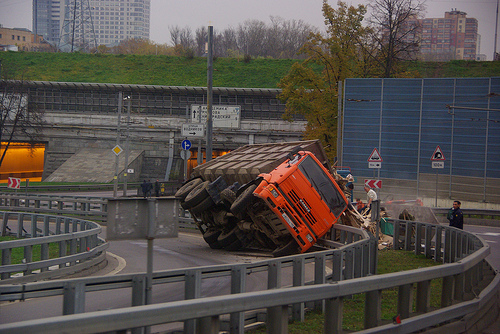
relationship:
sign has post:
[431, 146, 448, 163] [434, 171, 440, 222]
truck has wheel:
[173, 137, 349, 255] [233, 186, 256, 214]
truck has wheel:
[173, 137, 349, 255] [274, 238, 292, 256]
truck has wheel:
[173, 137, 349, 255] [188, 184, 213, 211]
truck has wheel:
[173, 137, 349, 255] [171, 179, 203, 197]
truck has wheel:
[173, 137, 349, 255] [217, 231, 243, 252]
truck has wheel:
[173, 137, 349, 255] [200, 226, 225, 251]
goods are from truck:
[310, 185, 477, 269] [127, 135, 357, 266]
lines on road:
[93, 249, 136, 279] [25, 205, 338, 330]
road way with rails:
[99, 208, 301, 280] [158, 250, 400, 324]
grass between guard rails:
[317, 237, 453, 327] [196, 219, 381, 284]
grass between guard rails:
[317, 237, 453, 327] [398, 219, 497, 324]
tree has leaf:
[278, 2, 388, 162] [323, 7, 328, 13]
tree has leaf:
[278, 2, 388, 162] [330, 26, 347, 37]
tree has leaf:
[278, 2, 388, 162] [356, 56, 370, 66]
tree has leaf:
[278, 2, 388, 162] [307, 38, 321, 50]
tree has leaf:
[278, 2, 388, 162] [300, 94, 319, 106]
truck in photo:
[173, 137, 349, 255] [4, 5, 490, 331]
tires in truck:
[178, 177, 295, 255] [173, 137, 349, 255]